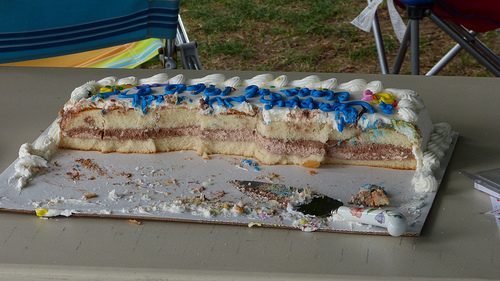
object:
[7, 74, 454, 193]
cake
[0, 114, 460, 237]
sheet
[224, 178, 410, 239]
cake cutter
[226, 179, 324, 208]
frosting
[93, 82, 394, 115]
words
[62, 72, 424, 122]
frosting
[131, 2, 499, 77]
grass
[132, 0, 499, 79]
ground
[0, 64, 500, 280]
table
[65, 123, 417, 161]
filling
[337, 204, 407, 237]
handle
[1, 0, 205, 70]
picnic chair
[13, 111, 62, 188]
frosting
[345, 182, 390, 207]
crumb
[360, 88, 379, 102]
icing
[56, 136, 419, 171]
layer